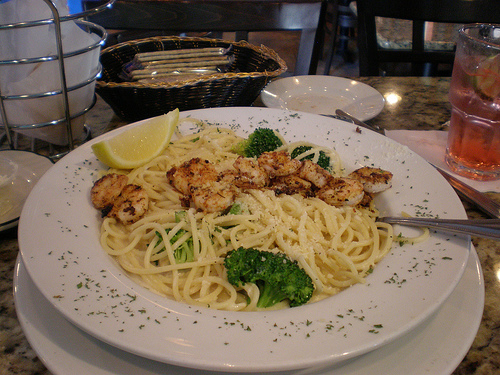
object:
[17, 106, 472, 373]
bowl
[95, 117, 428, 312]
pasta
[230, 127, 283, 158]
broccoli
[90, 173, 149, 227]
chicken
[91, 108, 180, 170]
lemon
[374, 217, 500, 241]
utensil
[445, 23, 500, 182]
glass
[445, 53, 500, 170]
liquid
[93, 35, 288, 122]
basket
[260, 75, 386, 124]
plate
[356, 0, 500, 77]
seat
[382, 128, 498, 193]
napkin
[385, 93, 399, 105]
glare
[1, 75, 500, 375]
table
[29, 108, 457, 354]
green spices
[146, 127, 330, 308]
broccoli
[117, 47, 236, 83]
crackers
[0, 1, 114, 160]
basket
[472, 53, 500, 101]
lime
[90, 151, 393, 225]
shrimp